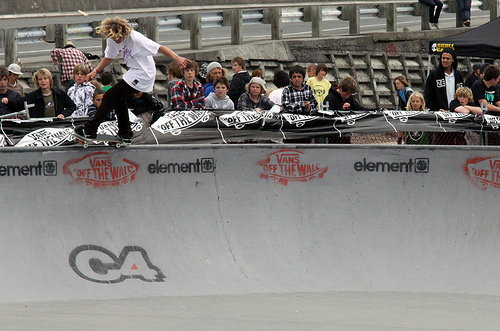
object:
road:
[0, 10, 496, 60]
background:
[1, 1, 498, 72]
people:
[0, 73, 26, 135]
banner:
[0, 110, 499, 148]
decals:
[13, 119, 76, 148]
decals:
[151, 110, 211, 135]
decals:
[218, 111, 273, 130]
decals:
[279, 112, 320, 139]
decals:
[430, 111, 472, 133]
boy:
[73, 17, 193, 144]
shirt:
[104, 29, 162, 93]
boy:
[280, 64, 319, 115]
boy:
[435, 86, 483, 145]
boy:
[204, 76, 235, 110]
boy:
[237, 77, 285, 114]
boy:
[67, 62, 97, 116]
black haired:
[289, 66, 306, 79]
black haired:
[273, 70, 291, 88]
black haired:
[100, 68, 111, 82]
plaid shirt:
[170, 78, 206, 109]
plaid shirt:
[280, 84, 319, 115]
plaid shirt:
[50, 47, 94, 82]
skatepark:
[0, 32, 499, 331]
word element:
[353, 157, 413, 173]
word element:
[146, 159, 201, 175]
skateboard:
[66, 129, 135, 149]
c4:
[69, 243, 168, 284]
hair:
[93, 19, 133, 41]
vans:
[256, 149, 327, 186]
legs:
[85, 79, 141, 138]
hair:
[315, 63, 328, 76]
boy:
[306, 63, 332, 109]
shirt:
[305, 76, 331, 110]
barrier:
[198, 50, 500, 109]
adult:
[424, 47, 466, 111]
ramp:
[0, 144, 500, 306]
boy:
[170, 59, 206, 110]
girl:
[402, 92, 445, 145]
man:
[23, 68, 76, 119]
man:
[50, 41, 94, 94]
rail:
[0, 0, 499, 63]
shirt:
[445, 69, 455, 109]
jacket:
[424, 48, 465, 111]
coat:
[423, 47, 465, 111]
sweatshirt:
[204, 91, 235, 109]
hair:
[405, 91, 426, 111]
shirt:
[403, 130, 430, 144]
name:
[147, 157, 215, 174]